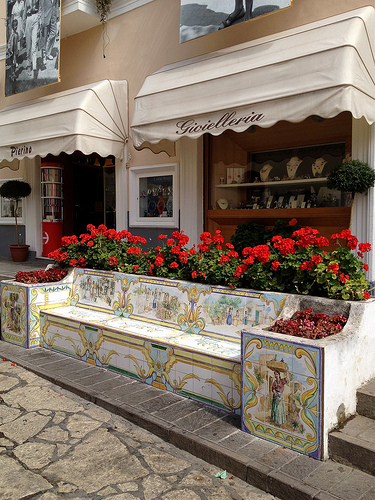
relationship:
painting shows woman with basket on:
[244, 337, 324, 459] [266, 355, 291, 429]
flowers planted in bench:
[46, 222, 371, 303] [0, 269, 373, 462]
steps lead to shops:
[331, 379, 374, 480] [0, 2, 373, 270]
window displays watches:
[203, 114, 349, 232] [239, 193, 318, 210]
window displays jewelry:
[203, 114, 349, 232] [221, 158, 333, 208]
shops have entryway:
[0, 2, 373, 270] [58, 166, 115, 242]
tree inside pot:
[2, 181, 31, 247] [10, 247, 29, 265]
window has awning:
[203, 114, 349, 232] [130, 7, 373, 156]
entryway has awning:
[58, 166, 115, 242] [2, 81, 129, 166]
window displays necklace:
[203, 114, 349, 232] [285, 159, 299, 171]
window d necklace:
[203, 114, 349, 232] [310, 158, 327, 170]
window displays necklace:
[203, 114, 349, 232] [262, 166, 272, 174]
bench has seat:
[0, 269, 373, 462] [45, 302, 241, 360]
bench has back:
[0, 269, 373, 462] [72, 269, 299, 347]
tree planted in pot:
[2, 181, 31, 247] [10, 247, 29, 265]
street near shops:
[0, 355, 279, 499] [0, 2, 373, 270]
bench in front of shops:
[0, 269, 373, 462] [0, 2, 373, 270]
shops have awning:
[0, 2, 373, 270] [130, 7, 373, 156]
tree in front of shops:
[2, 181, 31, 247] [0, 2, 373, 270]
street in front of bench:
[0, 355, 279, 499] [0, 269, 373, 462]